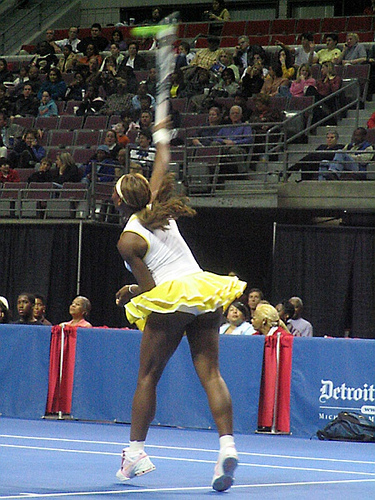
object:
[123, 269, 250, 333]
skirt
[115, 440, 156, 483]
shoe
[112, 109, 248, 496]
player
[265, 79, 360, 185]
wall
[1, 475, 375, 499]
lines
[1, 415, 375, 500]
floor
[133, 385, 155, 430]
calves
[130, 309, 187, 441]
leg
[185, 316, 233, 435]
leg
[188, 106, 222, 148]
woman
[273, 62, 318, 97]
woman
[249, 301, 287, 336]
spectator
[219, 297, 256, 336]
spectator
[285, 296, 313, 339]
spectator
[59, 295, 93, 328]
spectator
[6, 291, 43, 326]
spectator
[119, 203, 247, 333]
outfit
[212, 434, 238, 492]
shoe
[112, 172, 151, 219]
head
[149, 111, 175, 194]
right hand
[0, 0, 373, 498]
stadium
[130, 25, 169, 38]
ball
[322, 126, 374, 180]
audience member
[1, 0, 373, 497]
tennis match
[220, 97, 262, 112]
wall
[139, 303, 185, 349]
thigh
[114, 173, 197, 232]
hair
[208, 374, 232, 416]
calf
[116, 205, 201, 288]
top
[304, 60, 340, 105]
people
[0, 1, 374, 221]
bleachers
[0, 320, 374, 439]
box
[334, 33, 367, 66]
people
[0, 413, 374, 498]
tennis court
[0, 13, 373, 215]
seats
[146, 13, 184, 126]
racquet